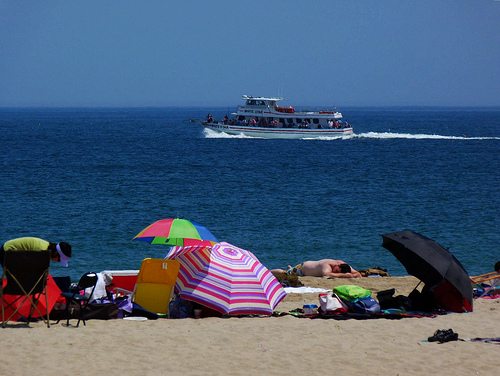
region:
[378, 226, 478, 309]
a black beach umbrella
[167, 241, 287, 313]
a striped beach umbrella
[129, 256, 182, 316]
a yellow beach chair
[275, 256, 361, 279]
a man laying on the beach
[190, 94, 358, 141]
a boat in the ocean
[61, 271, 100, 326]
a black chair on the beach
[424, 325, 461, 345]
a pair of black shoes in the sand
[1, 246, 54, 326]
a black beach chair in the sand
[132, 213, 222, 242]
a multi-colored beach umbrella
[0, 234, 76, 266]
a person bending over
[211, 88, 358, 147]
the boat is on the water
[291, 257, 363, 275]
the man is laying on the beach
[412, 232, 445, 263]
the umbrella is black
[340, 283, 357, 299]
the towel is nneon green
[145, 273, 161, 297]
the chair is yellow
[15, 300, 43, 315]
the umbrella is red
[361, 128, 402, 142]
the boat is making waves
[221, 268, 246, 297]
the umbrella has stripes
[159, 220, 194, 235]
the umbrella is multi color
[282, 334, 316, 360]
the sand is tan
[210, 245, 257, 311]
this is an umbrella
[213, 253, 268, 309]
the umbrella is colorful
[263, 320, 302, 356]
this is the beach sand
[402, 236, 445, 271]
the umbrella is black in color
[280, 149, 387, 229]
this is the sea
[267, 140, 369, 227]
the sea is calm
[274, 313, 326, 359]
the sand is brown in color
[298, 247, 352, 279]
this is a man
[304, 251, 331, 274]
then man is bare chested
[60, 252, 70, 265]
this is a cap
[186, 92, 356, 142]
white boat near sandy beach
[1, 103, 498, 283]
dark blue ocean near beach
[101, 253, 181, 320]
yellow folding beach chair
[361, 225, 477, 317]
circular black umbrella on beach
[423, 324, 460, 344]
black shoes on beach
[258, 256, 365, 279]
man wearing swim trunks sleeping on beach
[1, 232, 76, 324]
person wearing visor and green shirt bending down on beach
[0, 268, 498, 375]
beige sandy beach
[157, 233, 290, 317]
large circular red white purple and blue umbrella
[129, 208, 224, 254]
circular blue green and red umbrella on beach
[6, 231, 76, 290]
person behind the chair leaning down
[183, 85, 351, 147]
boat on the water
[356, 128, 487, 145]
wake left by the boat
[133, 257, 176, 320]
yellow chair on the beach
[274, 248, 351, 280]
pale person sun bathing on the beach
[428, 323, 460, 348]
shoes sitting on the sand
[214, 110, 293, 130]
people on the boat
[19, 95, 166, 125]
horizon line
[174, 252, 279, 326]
striped umbrella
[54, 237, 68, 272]
person is wearing a visor